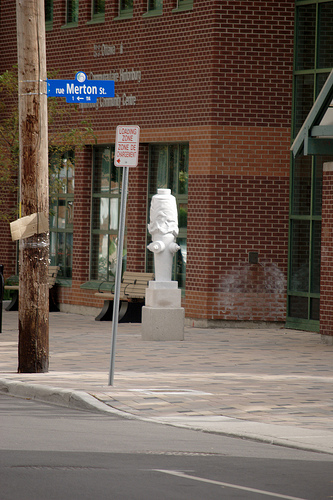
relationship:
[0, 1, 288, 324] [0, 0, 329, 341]
brick wall of building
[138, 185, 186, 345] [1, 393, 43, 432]
statue in middle of street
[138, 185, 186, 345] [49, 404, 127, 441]
statue in middle of street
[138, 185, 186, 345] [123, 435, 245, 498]
statue in middle of street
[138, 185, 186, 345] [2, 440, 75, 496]
statue in middle of street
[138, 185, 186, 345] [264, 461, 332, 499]
statue in middle of street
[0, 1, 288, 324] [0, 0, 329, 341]
brick wall on building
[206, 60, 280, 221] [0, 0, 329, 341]
brick wall on building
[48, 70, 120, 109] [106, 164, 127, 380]
blue sky on post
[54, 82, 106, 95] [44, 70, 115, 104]
name on sign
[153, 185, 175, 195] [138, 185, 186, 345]
top on statue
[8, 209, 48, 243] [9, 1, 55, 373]
cardboard on pole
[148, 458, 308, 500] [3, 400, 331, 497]
line on road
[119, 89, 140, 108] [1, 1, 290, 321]
word on building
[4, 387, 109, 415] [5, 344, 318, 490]
curb near street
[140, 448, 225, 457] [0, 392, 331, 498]
manhole on street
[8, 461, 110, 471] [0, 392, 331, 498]
manhole on street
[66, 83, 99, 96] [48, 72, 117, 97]
letters in sign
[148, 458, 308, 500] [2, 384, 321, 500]
line on street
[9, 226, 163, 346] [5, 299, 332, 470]
benches on sidewalk